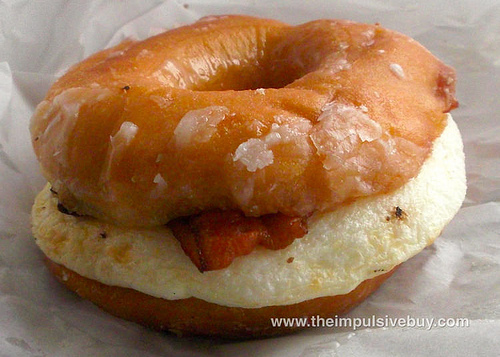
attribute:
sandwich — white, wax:
[49, 40, 428, 271]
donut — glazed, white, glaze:
[28, 12, 456, 208]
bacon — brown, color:
[163, 207, 313, 275]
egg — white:
[102, 251, 406, 299]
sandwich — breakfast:
[97, 74, 331, 324]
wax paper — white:
[417, 246, 497, 347]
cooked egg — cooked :
[39, 17, 480, 316]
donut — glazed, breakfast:
[30, 13, 468, 339]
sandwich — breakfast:
[246, 91, 425, 317]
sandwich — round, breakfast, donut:
[18, 7, 471, 339]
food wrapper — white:
[0, 0, 499, 356]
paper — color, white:
[3, 2, 499, 351]